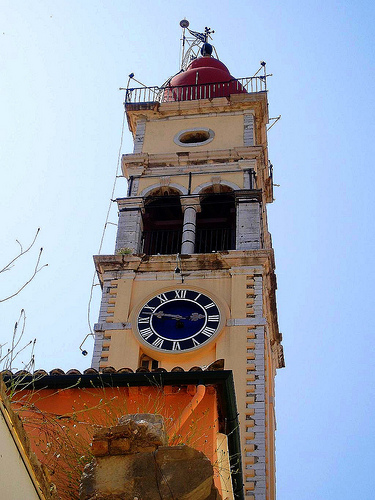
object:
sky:
[0, 2, 373, 498]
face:
[149, 300, 205, 340]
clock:
[136, 289, 221, 353]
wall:
[211, 115, 239, 142]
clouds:
[309, 330, 369, 399]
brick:
[245, 270, 266, 287]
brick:
[245, 288, 265, 298]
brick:
[246, 334, 268, 346]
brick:
[241, 398, 268, 413]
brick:
[241, 460, 267, 471]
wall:
[114, 267, 157, 307]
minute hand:
[141, 310, 182, 319]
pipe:
[270, 162, 274, 203]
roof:
[122, 72, 270, 119]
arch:
[137, 184, 183, 253]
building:
[90, 19, 284, 500]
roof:
[2, 358, 232, 391]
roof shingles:
[167, 365, 200, 375]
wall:
[131, 167, 253, 189]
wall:
[150, 383, 217, 438]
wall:
[214, 116, 246, 151]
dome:
[152, 40, 251, 104]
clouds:
[24, 28, 104, 128]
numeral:
[171, 341, 181, 351]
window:
[178, 130, 211, 144]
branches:
[0, 227, 120, 499]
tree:
[2, 215, 98, 500]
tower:
[84, 41, 283, 498]